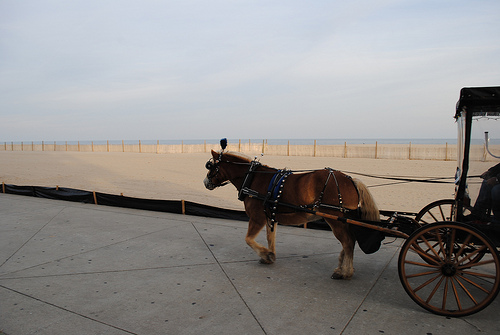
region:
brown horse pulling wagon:
[198, 141, 395, 272]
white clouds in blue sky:
[142, 33, 170, 50]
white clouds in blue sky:
[301, 58, 388, 110]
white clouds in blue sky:
[397, 12, 439, 60]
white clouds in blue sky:
[274, 29, 348, 83]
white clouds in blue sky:
[194, 25, 248, 72]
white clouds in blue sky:
[102, 43, 167, 93]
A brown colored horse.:
[203, 136, 381, 278]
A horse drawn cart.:
[297, 83, 499, 318]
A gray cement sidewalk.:
[0, 193, 499, 334]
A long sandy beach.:
[0, 142, 455, 222]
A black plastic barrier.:
[0, 180, 250, 222]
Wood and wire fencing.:
[0, 137, 220, 159]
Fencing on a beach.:
[225, 138, 460, 163]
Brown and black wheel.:
[396, 222, 498, 317]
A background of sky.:
[0, 0, 499, 139]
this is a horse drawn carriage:
[147, 43, 498, 322]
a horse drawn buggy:
[167, 20, 498, 324]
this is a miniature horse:
[164, 108, 386, 297]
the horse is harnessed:
[172, 108, 420, 293]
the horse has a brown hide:
[171, 114, 402, 296]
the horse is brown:
[179, 121, 399, 287]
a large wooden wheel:
[385, 210, 499, 325]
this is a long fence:
[1, 129, 498, 181]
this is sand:
[73, 150, 214, 186]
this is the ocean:
[7, 110, 499, 152]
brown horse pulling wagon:
[194, 131, 366, 275]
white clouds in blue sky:
[107, 33, 147, 67]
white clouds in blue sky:
[208, 38, 255, 59]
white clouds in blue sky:
[70, 83, 122, 143]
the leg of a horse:
[245, 210, 276, 266]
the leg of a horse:
[257, 217, 278, 266]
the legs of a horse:
[327, 224, 357, 281]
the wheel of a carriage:
[390, 216, 499, 322]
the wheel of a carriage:
[408, 196, 488, 273]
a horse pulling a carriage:
[194, 85, 498, 318]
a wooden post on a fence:
[370, 139, 382, 159]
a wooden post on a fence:
[407, 139, 414, 162]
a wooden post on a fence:
[444, 139, 449, 161]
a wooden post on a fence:
[155, 139, 159, 153]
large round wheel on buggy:
[396, 222, 496, 317]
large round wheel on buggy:
[415, 200, 485, 265]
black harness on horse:
[205, 154, 247, 181]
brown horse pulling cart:
[179, 123, 384, 280]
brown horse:
[198, 130, 387, 285]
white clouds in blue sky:
[45, 34, 77, 59]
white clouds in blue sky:
[161, 19, 211, 63]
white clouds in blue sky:
[306, 44, 343, 74]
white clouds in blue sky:
[383, 22, 435, 67]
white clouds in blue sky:
[177, 61, 219, 84]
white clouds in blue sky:
[261, 69, 292, 92]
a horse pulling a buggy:
[191, 136, 496, 322]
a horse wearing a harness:
[225, 148, 349, 258]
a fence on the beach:
[142, 124, 452, 205]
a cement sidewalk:
[81, 204, 274, 325]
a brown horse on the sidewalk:
[236, 142, 386, 310]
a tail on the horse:
[335, 150, 399, 257]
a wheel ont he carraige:
[408, 223, 497, 291]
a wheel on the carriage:
[424, 183, 495, 263]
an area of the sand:
[122, 137, 199, 193]